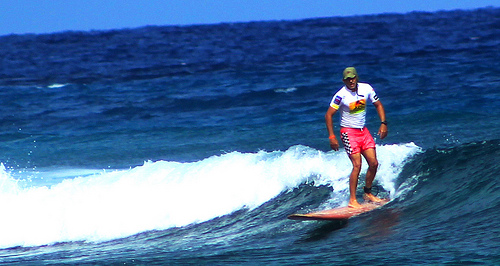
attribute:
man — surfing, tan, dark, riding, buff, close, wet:
[312, 59, 396, 191]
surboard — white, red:
[295, 203, 388, 230]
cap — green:
[340, 60, 364, 88]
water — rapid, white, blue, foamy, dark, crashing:
[108, 32, 277, 181]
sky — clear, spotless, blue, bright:
[154, 0, 211, 26]